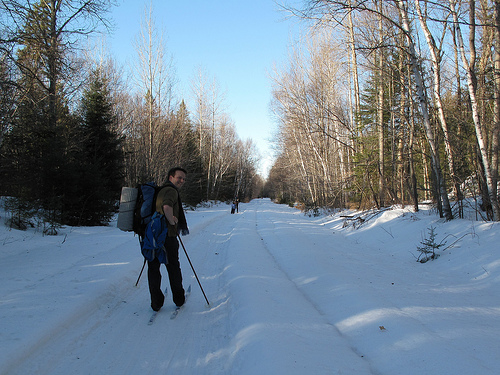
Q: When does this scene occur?
A: Daytime.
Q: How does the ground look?
A: Covered in snow.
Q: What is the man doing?
A: Cross country skiing.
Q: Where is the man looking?
A: At the camera.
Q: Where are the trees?
A: On both sides of the road.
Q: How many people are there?
A: Two.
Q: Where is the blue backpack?
A: On the man's back.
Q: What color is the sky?
A: Blue.